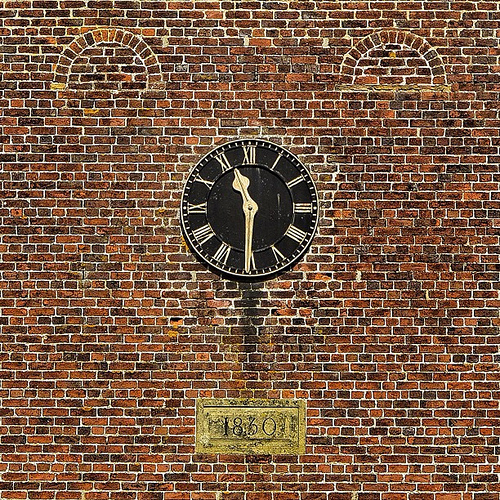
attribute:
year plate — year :
[191, 394, 309, 459]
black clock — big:
[179, 137, 319, 276]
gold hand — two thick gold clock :
[231, 167, 256, 211]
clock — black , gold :
[170, 125, 330, 288]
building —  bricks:
[2, 0, 496, 497]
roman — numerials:
[270, 223, 305, 261]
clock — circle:
[163, 115, 344, 299]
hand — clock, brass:
[231, 166, 259, 211]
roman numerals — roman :
[183, 182, 215, 254]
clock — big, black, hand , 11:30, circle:
[179, 140, 317, 280]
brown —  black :
[343, 268, 486, 435]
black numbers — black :
[219, 417, 280, 436]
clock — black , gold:
[176, 130, 325, 285]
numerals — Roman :
[211, 152, 240, 172]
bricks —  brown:
[334, 347, 415, 383]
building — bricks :
[381, 276, 431, 368]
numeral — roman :
[247, 248, 263, 265]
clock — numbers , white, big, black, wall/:
[172, 134, 326, 295]